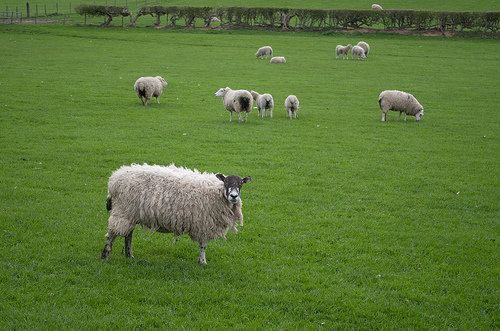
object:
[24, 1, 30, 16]
pole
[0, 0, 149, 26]
fence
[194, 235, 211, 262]
legs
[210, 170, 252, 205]
head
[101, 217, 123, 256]
leg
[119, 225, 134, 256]
leg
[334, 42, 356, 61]
sheep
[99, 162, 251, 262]
sheep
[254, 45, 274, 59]
sheep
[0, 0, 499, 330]
grass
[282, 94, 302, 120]
sheep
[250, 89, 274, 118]
sheep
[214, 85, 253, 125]
sheep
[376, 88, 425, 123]
sheep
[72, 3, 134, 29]
plants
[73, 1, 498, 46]
trees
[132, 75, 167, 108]
gray sheep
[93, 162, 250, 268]
gray sheep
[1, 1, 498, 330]
green field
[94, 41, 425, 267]
herd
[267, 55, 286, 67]
sheep